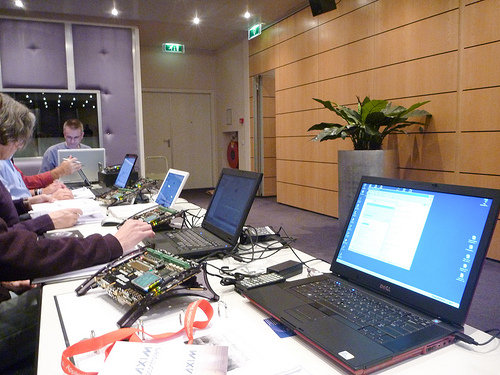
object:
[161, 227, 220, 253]
keyboard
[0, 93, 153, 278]
people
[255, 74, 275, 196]
door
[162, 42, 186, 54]
sign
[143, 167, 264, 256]
laptop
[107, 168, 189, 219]
laptop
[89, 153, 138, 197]
laptop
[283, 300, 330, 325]
pad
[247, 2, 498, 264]
wall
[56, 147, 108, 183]
computer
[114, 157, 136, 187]
screen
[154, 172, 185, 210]
screen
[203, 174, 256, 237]
screen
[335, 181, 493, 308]
screen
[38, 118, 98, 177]
man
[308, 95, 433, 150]
green plant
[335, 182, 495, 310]
silver planter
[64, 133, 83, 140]
glasses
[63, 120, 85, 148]
head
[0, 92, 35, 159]
head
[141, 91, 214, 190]
door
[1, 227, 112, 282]
arm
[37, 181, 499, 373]
table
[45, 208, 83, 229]
hand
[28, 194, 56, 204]
hand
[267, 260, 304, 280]
charger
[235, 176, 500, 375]
laptop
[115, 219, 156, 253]
hand